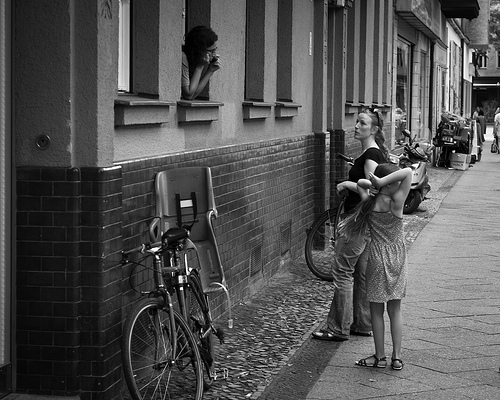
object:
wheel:
[118, 293, 208, 400]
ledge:
[174, 97, 226, 125]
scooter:
[399, 128, 437, 214]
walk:
[115, 100, 451, 400]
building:
[0, 0, 484, 400]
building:
[0, 0, 488, 400]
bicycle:
[116, 226, 218, 400]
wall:
[96, 131, 319, 400]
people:
[475, 108, 486, 142]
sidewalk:
[252, 126, 500, 400]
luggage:
[440, 111, 468, 130]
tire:
[302, 211, 343, 282]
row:
[114, 101, 303, 128]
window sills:
[114, 100, 173, 126]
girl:
[351, 161, 415, 371]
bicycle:
[301, 151, 401, 282]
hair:
[351, 163, 400, 234]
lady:
[313, 110, 394, 344]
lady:
[178, 23, 224, 102]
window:
[178, 0, 225, 123]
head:
[352, 106, 387, 142]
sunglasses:
[364, 108, 382, 128]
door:
[394, 47, 409, 148]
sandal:
[354, 354, 389, 370]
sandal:
[390, 357, 404, 370]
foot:
[355, 354, 387, 368]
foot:
[391, 358, 403, 370]